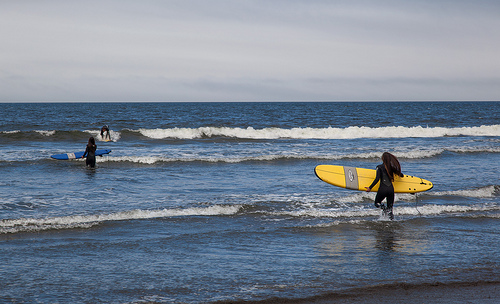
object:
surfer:
[364, 152, 403, 220]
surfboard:
[51, 149, 111, 160]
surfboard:
[314, 164, 434, 195]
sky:
[2, 2, 494, 101]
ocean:
[0, 101, 498, 234]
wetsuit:
[369, 163, 404, 214]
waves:
[140, 124, 500, 140]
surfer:
[101, 124, 111, 139]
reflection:
[373, 221, 394, 252]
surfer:
[82, 136, 97, 167]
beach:
[252, 266, 499, 304]